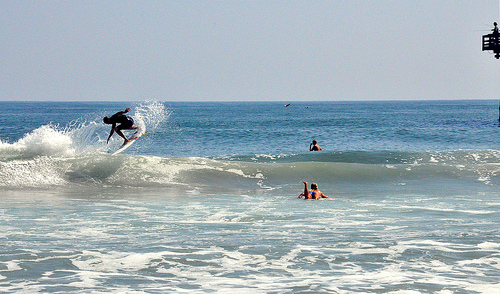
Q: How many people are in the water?
A: Three.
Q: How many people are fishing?
A: One.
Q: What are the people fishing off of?
A: A pier.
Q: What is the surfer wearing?
A: A wetsuit.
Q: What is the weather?
A: Sunny.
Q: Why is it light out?
A: It's daytime.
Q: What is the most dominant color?
A: Blue.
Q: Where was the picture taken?
A: The ocean.